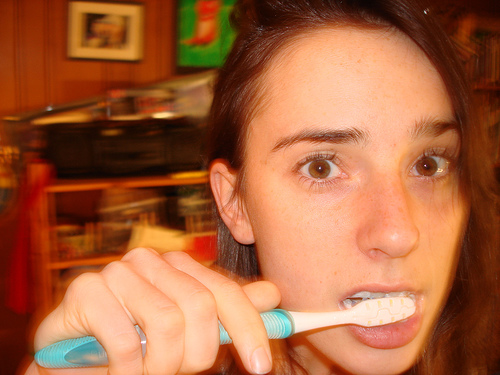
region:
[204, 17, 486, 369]
A woman with brown hair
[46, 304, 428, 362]
White and blue toothbrush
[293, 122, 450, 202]
Woman with brown eyes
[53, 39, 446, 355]
Woman is holding a toothbrush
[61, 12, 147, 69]
Black and white picture frame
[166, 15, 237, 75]
Green, red, and yellow picture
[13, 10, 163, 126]
The wall is brown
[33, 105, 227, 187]
A black radio on a cabinet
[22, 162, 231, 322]
The cabinet is brown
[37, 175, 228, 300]
There are items on the cabinet shelves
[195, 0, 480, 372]
the head of a woman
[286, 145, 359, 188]
the eye of a woman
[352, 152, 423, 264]
the nose of a woman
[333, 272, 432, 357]
the mouth of a woman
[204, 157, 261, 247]
the ear of a woman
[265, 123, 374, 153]
the eyebrow of a woman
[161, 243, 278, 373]
the finger of a woman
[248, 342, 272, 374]
the fingernail of a woman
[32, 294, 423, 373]
a blue and white toothbrush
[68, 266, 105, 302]
the knuckle of a woman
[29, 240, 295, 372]
the hand of a woman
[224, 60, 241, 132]
the hair is black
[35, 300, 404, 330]
the tooth brush is blue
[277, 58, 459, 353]
the face is brown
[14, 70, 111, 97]
the wall is wooden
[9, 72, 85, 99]
the wall is brown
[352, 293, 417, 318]
the teeth are white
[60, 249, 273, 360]
the fingers are five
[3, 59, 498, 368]
the photo was taken indoors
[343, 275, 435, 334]
the mouth is open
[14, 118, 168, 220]
the photo is blurr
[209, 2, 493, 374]
young girl's oval face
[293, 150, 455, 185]
girl's eyes are hazel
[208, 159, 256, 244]
the girl's right ear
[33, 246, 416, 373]
girl's hand holding blue and white toothbrush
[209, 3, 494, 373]
girl's right eye is open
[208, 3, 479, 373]
girl's left eye is open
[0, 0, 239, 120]
green painting of a red fox on a wood paneled wall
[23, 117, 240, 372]
stereo system on the bookshelf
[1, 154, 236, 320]
red dress hanging on the bookshelf side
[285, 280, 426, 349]
pink lips and red teeth around white toothbrush head